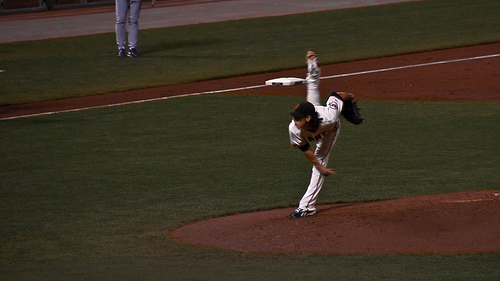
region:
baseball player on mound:
[257, 30, 390, 211]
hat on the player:
[283, 100, 311, 121]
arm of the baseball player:
[301, 153, 328, 181]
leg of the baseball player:
[282, 180, 328, 227]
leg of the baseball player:
[302, 48, 323, 95]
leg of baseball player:
[111, 43, 129, 58]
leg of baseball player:
[123, 38, 156, 65]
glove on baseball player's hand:
[343, 104, 363, 126]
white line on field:
[364, 63, 381, 77]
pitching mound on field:
[344, 214, 471, 242]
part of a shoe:
[293, 201, 300, 219]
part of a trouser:
[303, 182, 313, 207]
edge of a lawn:
[180, 181, 205, 216]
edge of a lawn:
[185, 188, 204, 234]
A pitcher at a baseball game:
[278, 46, 370, 227]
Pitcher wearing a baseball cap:
[283, 93, 325, 150]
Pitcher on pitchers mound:
[181, 184, 498, 252]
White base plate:
[265, 56, 305, 97]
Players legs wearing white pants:
[106, 3, 158, 61]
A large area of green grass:
[49, 127, 175, 194]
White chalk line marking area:
[111, 80, 248, 107]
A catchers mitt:
[340, 93, 371, 127]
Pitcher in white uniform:
[280, 49, 349, 218]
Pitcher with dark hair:
[290, 90, 330, 142]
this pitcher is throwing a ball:
[25, 18, 464, 275]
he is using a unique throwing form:
[279, 52, 363, 222]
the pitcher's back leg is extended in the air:
[292, 50, 344, 127]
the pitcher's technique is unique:
[255, 69, 371, 211]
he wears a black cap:
[276, 101, 336, 151]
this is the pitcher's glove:
[334, 85, 371, 130]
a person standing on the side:
[101, 1, 151, 63]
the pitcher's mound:
[158, 158, 498, 270]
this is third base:
[223, 52, 326, 91]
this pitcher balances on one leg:
[260, 133, 357, 228]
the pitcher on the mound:
[242, 30, 379, 228]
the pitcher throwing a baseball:
[268, 34, 377, 251]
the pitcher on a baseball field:
[274, 38, 413, 246]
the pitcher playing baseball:
[251, 47, 413, 221]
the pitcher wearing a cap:
[283, 90, 329, 147]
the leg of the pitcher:
[286, 43, 341, 100]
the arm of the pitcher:
[298, 138, 336, 187]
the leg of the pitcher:
[288, 144, 334, 220]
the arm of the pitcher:
[323, 89, 359, 116]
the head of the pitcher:
[291, 95, 329, 145]